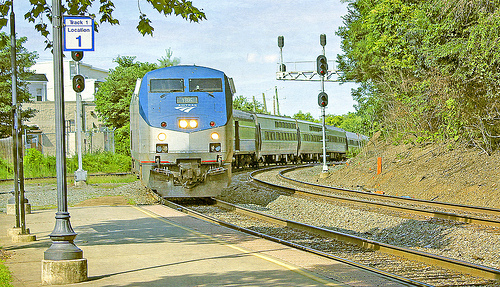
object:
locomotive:
[129, 65, 228, 198]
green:
[270, 0, 488, 145]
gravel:
[183, 196, 318, 222]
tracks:
[273, 173, 332, 245]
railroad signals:
[316, 56, 328, 108]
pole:
[317, 47, 328, 172]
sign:
[62, 17, 94, 52]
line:
[137, 207, 222, 243]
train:
[130, 65, 370, 197]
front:
[132, 65, 227, 193]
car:
[130, 65, 368, 197]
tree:
[334, 0, 495, 137]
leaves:
[0, 0, 500, 175]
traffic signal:
[317, 92, 328, 106]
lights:
[178, 118, 198, 128]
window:
[150, 78, 220, 93]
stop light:
[73, 74, 85, 93]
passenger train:
[131, 65, 367, 195]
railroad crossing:
[297, 223, 360, 255]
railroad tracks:
[176, 159, 500, 286]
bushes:
[0, 32, 179, 178]